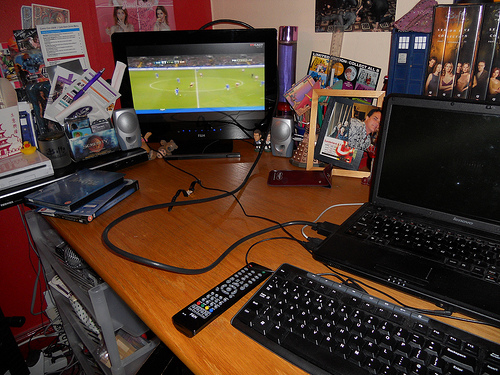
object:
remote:
[172, 262, 272, 339]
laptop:
[315, 97, 499, 324]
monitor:
[111, 28, 278, 140]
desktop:
[41, 138, 500, 374]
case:
[267, 164, 333, 188]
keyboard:
[233, 263, 499, 375]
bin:
[25, 214, 160, 374]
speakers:
[271, 117, 293, 157]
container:
[0, 77, 24, 161]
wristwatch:
[167, 180, 200, 211]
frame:
[307, 89, 387, 178]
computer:
[111, 28, 277, 140]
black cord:
[102, 121, 315, 275]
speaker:
[113, 108, 142, 150]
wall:
[0, 1, 212, 79]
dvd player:
[0, 151, 55, 188]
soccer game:
[129, 45, 266, 112]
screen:
[378, 104, 500, 226]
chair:
[0, 315, 27, 375]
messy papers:
[34, 23, 91, 72]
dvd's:
[26, 170, 124, 213]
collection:
[422, 0, 500, 102]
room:
[0, 0, 500, 375]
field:
[129, 66, 265, 115]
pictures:
[312, 95, 378, 172]